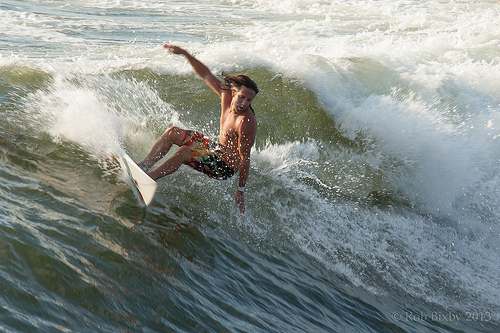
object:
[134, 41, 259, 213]
surfer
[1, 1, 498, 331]
ocean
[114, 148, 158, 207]
surfboard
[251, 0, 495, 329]
wave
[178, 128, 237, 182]
shorts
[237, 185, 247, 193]
watch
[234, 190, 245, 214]
hand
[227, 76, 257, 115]
head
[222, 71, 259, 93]
hair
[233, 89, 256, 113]
face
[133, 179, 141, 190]
logo